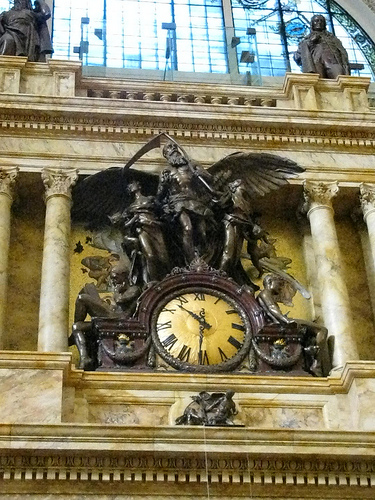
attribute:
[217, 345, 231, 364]
roman numeral — small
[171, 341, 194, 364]
roman numeral — small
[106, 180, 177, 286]
statue — bronze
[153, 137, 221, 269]
statue — bronze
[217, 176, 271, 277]
statue — bronze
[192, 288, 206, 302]
numeral — small, roman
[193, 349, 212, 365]
numeral — small, roman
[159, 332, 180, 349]
numeral — roman, small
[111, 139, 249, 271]
statues — people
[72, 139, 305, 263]
statue — BROWN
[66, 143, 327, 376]
sculptures — CLUSTER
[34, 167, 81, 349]
column — TALL, MARBLE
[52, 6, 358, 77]
glass panels — BLUE, STAINED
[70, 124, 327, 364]
statues — SCULPTED, CLOCK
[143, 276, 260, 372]
clock — OLD, BRONZE, ROMAN NUMERAL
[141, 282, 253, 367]
clock — OLD WORLD STYLE, WALL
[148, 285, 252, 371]
clock — WALL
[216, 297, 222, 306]
numeral — Small 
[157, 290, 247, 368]
clock — Black and yellow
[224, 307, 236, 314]
numeral — Small 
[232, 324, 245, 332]
numeral — Small 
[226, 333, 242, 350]
numeral — Small 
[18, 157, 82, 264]
pillar — old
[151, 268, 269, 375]
clock — yellow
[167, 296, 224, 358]
hands — black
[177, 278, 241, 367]
face — gold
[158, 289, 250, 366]
numerals — black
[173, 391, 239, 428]
statue — small, brown, metal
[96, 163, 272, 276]
statue — large, brown, metal